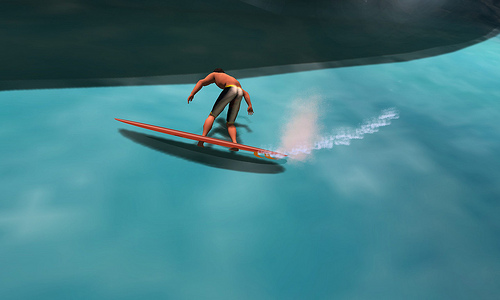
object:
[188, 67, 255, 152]
man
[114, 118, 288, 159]
surfboard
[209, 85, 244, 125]
shorts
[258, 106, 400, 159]
spray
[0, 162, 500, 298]
water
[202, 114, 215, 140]
leg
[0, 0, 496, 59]
water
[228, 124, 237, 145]
leg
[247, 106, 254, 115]
hand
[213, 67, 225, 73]
head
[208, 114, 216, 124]
knee